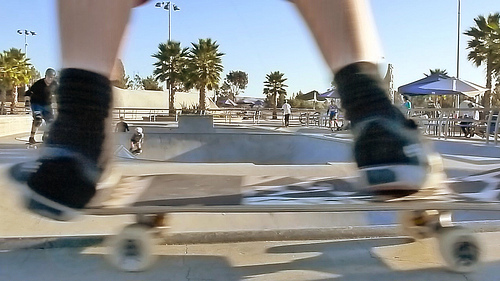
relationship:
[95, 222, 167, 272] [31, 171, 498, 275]
wheel under skateboard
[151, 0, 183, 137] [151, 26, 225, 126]
lamp post near trees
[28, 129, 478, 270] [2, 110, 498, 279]
skateboard on ground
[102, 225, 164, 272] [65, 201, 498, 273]
wheel on skateboard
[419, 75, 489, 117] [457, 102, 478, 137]
umbrella standing near person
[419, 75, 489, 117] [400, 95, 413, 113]
umbrella standing near person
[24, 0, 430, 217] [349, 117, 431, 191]
person wearing shoes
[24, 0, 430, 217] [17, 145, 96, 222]
person wearing shoes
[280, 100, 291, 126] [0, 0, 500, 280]
man at park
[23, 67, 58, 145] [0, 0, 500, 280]
kid at park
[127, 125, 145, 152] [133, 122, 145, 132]
kid wearing helmet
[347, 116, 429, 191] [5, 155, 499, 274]
foot on skateboard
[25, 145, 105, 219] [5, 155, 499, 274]
foot on skateboard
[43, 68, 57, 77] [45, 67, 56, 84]
helmet on head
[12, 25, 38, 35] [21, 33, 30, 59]
lights on pole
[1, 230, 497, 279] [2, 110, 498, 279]
shadow on ground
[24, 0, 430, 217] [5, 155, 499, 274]
person on skateboard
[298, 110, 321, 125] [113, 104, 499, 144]
bicycle by fence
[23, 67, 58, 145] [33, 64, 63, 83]
kid wears helmet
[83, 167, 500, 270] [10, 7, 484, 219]
skateboard beneath person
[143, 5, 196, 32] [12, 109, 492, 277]
lights for skatepark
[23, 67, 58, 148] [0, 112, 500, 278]
kid skateboarding at park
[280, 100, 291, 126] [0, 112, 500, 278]
man skateboarding at park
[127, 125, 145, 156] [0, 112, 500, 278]
kid skateboarding at park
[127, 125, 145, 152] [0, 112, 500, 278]
kid skateboarding at park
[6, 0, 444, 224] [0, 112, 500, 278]
person skateboarding at park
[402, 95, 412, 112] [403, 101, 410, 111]
man with shirt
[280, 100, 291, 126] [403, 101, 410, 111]
man with shirt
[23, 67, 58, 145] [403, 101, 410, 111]
kid with shirt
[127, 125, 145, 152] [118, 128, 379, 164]
kid in bowl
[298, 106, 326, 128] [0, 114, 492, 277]
bicycle outside skatepark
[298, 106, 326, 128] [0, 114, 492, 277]
bicycle parked outside skatepark